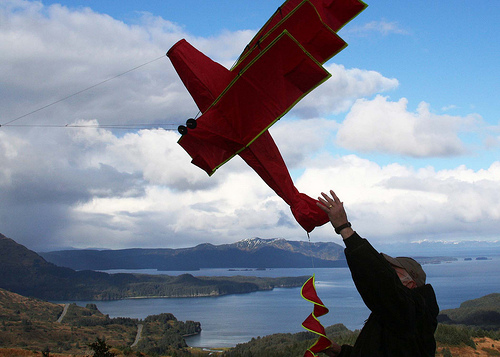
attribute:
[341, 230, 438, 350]
jacket — black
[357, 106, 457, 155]
cloud — white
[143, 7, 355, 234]
kite — red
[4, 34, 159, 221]
clouds — white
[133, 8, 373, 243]
plane — red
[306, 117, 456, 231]
clouds — fluffy, white 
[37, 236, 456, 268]
mountains — large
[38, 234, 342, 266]
mountains — majestic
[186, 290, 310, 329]
lake water — calm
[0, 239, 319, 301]
peninsula — wooded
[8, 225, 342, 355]
mountains — snow-covered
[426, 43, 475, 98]
sky — blue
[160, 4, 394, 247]
kite — red, airplane-shaped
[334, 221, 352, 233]
watch — black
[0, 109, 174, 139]
string — small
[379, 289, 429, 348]
jacket — dark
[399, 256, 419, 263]
cap — ball